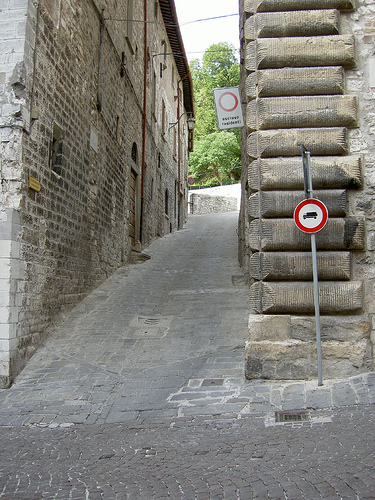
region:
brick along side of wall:
[251, 9, 334, 35]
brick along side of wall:
[255, 34, 351, 60]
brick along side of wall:
[242, 69, 342, 90]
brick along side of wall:
[247, 156, 353, 181]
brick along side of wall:
[245, 277, 358, 310]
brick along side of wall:
[259, 250, 336, 275]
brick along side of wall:
[248, 221, 352, 247]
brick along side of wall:
[248, 96, 346, 129]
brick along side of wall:
[32, 210, 71, 297]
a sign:
[271, 141, 334, 394]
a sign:
[240, 137, 367, 419]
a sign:
[223, 85, 330, 360]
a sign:
[289, 73, 365, 352]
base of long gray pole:
[302, 357, 334, 391]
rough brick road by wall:
[87, 425, 308, 495]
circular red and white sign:
[283, 188, 334, 233]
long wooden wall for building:
[229, 61, 369, 322]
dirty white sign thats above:
[213, 96, 260, 147]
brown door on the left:
[117, 156, 148, 254]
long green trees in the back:
[186, 55, 245, 186]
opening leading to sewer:
[265, 405, 331, 443]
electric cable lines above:
[170, 18, 232, 69]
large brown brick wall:
[36, 42, 161, 271]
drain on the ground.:
[276, 406, 312, 426]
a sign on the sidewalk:
[296, 145, 338, 388]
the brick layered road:
[176, 430, 328, 499]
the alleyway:
[146, 199, 244, 375]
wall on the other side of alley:
[190, 182, 239, 213]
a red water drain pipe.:
[138, 1, 142, 211]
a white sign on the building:
[205, 82, 242, 142]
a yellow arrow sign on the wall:
[26, 171, 41, 190]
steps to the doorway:
[124, 240, 145, 263]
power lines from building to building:
[102, 8, 242, 62]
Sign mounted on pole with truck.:
[294, 201, 326, 231]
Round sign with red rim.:
[293, 197, 331, 232]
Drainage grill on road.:
[275, 411, 306, 422]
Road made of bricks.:
[204, 409, 257, 496]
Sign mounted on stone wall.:
[212, 88, 245, 130]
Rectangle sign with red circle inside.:
[208, 88, 242, 128]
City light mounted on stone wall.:
[167, 109, 197, 129]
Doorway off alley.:
[129, 168, 137, 247]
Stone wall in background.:
[193, 193, 236, 213]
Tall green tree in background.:
[195, 46, 238, 179]